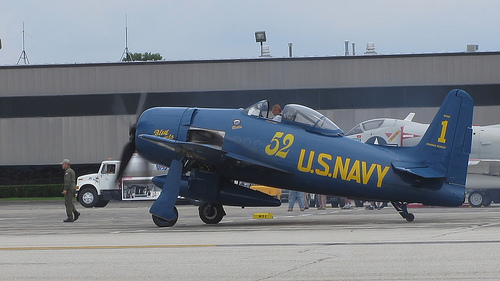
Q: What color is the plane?
A: Blue.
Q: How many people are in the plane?
A: One.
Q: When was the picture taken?
A: Daytime.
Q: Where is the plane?
A: At the airfield.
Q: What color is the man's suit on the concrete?
A: Green.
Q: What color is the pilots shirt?
A: White.